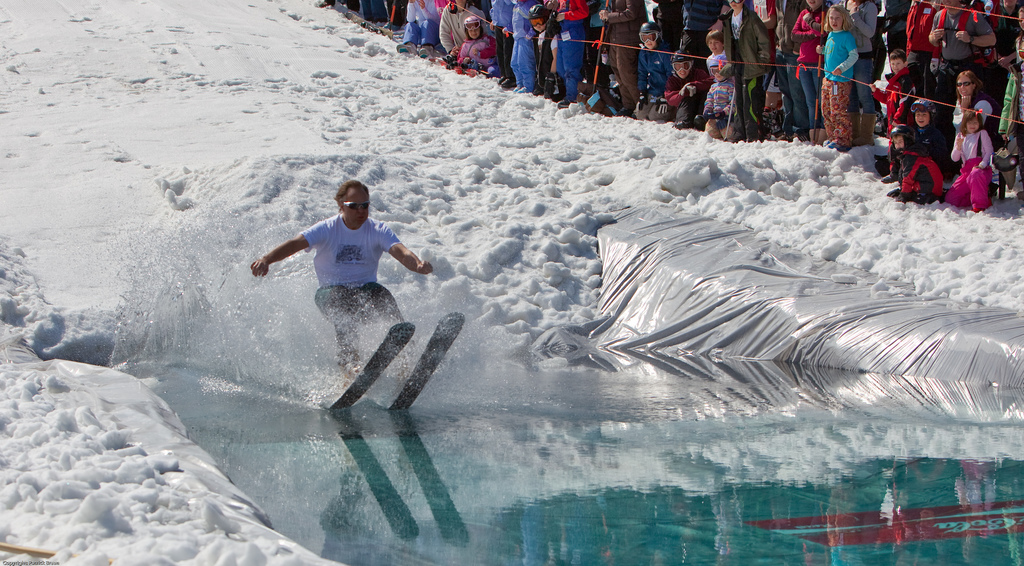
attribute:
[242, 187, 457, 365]
shirt — white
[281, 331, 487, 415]
skis — water